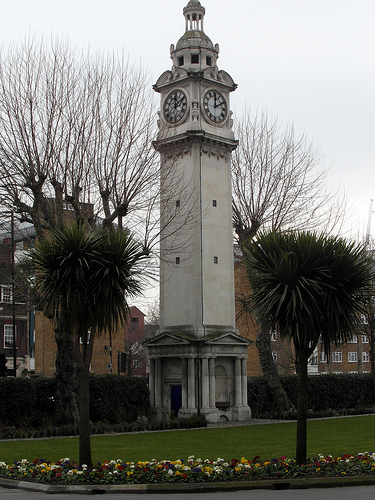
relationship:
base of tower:
[141, 328, 253, 427] [145, 1, 251, 426]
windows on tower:
[173, 199, 182, 209] [145, 1, 251, 426]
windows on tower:
[172, 255, 182, 265] [145, 1, 251, 426]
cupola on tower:
[180, 2, 207, 31] [145, 1, 251, 426]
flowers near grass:
[1, 449, 375, 485] [2, 411, 374, 474]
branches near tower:
[215, 105, 349, 250] [145, 1, 251, 426]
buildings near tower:
[225, 242, 375, 383] [145, 1, 251, 426]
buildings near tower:
[33, 192, 127, 381] [145, 1, 251, 426]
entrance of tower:
[166, 381, 184, 422] [145, 1, 251, 426]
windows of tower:
[173, 199, 182, 209] [145, 1, 251, 426]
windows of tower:
[172, 255, 182, 265] [145, 1, 251, 426]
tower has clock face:
[145, 1, 251, 426] [200, 85, 230, 127]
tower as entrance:
[145, 1, 251, 426] [166, 381, 184, 422]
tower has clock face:
[145, 1, 251, 426] [161, 87, 189, 127]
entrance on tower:
[166, 381, 184, 422] [145, 1, 251, 426]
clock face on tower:
[200, 85, 230, 127] [145, 1, 251, 426]